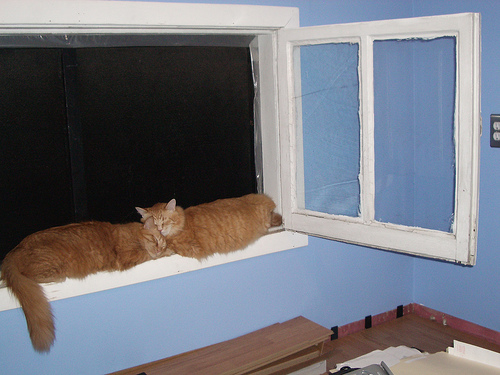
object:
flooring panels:
[98, 314, 338, 373]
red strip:
[410, 299, 500, 346]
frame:
[0, 8, 486, 311]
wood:
[330, 308, 499, 363]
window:
[0, 21, 274, 268]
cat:
[0, 222, 169, 357]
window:
[291, 35, 364, 224]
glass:
[370, 36, 462, 238]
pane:
[365, 29, 463, 239]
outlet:
[487, 112, 500, 151]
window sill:
[0, 227, 290, 311]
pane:
[292, 40, 361, 225]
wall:
[410, 0, 500, 342]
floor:
[322, 311, 497, 373]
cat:
[134, 192, 281, 263]